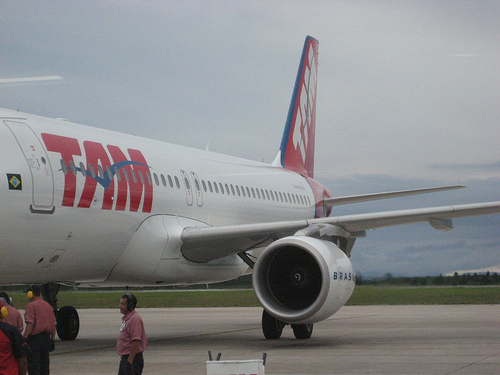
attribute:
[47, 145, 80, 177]
window — side window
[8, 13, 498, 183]
clouds — white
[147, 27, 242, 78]
clouds — white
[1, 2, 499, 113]
sky — blue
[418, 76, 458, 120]
cloud — white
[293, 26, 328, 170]
tail — red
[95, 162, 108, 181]
window — side window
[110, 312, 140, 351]
shirt — pink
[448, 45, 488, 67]
clouds — white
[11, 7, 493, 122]
sky — blue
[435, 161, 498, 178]
cloud — white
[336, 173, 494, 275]
cloud — white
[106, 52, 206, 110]
clouds — white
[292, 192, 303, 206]
window — side window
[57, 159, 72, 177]
window — side window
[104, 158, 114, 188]
window — side window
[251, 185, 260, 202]
window — side window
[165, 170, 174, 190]
window — side window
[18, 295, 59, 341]
shirt — pink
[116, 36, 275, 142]
clouds — white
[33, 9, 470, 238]
sky — blue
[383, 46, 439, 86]
sky — blue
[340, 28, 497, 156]
clouds — white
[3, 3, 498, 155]
sky — blue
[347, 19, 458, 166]
sky — blue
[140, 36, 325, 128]
clouds — white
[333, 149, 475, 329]
clouds — white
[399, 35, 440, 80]
sky — blue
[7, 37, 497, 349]
plane — red and white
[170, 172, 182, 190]
window — side window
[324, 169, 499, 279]
clouds — white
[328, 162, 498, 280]
cloud — white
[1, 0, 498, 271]
sky — blue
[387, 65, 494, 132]
sky — blue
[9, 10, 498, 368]
airplane — white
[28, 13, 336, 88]
sky — blue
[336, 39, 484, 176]
clouds — white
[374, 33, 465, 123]
clouds — white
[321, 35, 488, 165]
clouds — white